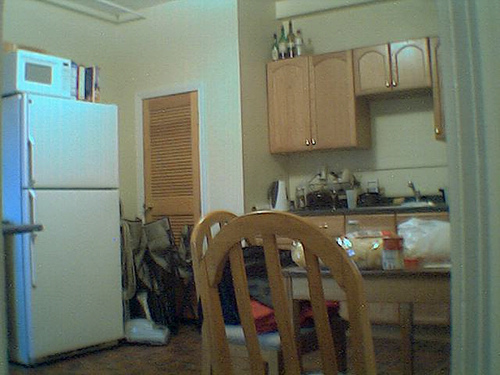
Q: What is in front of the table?
A: Light wooden chair back.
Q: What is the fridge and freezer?
A: White refrigerator and freezer.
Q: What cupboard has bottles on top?
A: The upper ones to the left.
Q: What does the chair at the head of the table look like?
A: Wood with a padded seat cushion.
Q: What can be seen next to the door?
A: Folded brown chairs.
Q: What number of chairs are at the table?
A: Two.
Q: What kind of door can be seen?
A: A brown one with slats on it.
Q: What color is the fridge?
A: White.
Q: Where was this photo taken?
A: A kitchen.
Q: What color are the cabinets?
A: Brown.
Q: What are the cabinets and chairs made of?
A: Wood.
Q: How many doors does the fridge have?
A: Two.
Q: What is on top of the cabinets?
A: Bottles.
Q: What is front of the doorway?
A: Folding chairs.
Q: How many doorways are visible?
A: One.